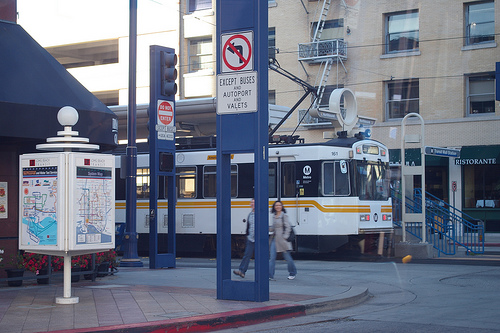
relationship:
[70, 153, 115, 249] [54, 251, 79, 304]
map displayed on pole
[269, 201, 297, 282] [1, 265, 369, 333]
woman on sidewalk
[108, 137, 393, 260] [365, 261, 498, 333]
tram at intersection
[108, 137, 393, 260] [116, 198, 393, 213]
tram has stripe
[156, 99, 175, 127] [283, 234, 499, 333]
sign on intersection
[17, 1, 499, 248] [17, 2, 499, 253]
building in background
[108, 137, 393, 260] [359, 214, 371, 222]
bus has headlight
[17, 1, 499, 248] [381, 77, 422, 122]
building has window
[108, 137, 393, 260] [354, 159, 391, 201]
tram has windshield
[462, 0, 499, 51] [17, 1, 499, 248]
window on building